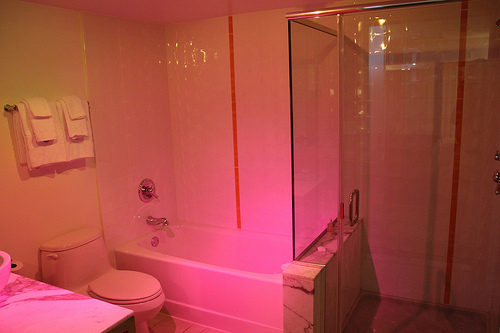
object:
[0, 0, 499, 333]
bathroom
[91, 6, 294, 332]
shower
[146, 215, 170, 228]
bath faucet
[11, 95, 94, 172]
towels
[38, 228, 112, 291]
tank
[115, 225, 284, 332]
bath tub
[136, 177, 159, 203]
fixtures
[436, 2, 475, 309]
stripe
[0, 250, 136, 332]
sink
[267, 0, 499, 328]
wall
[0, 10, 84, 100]
salmon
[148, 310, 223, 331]
floor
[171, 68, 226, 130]
tiles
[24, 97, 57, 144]
wash cloth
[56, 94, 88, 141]
wash cloth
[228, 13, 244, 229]
line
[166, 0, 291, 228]
bathtub wall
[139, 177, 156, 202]
handle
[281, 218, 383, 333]
marble wall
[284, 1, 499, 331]
shower stall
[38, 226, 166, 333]
toilet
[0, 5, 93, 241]
wall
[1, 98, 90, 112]
rack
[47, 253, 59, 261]
handle